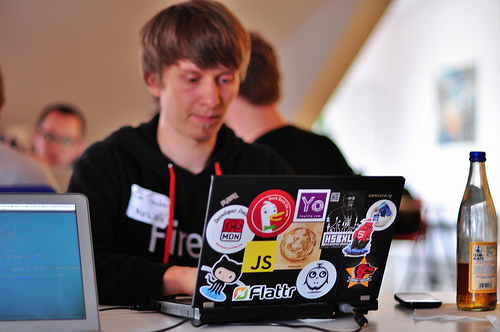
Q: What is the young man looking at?
A: Laptop.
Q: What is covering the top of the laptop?
A: Stickers.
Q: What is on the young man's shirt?
A: Sticker.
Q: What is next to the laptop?
A: Phone.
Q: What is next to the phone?
A: Beverage.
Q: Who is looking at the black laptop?
A: Young man.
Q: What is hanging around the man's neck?
A: Red string.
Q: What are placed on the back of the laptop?
A: Stickers.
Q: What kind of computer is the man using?
A: A laptop.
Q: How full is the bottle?
A: About half full.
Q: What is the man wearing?
A: A hoodie.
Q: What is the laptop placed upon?
A: A table.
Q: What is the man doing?
A: Typing.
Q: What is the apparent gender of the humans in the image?
A: Male.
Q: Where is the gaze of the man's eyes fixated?
A: The laptop screen.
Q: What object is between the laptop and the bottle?
A: A phone.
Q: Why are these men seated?
A: To be on their computers.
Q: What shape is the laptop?
A: Square.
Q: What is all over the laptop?
A: Stickers.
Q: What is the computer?
A: Laptop.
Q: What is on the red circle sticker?
A: Duck.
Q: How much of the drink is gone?
A: Half.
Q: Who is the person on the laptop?
A: Boy.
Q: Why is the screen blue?
A: On.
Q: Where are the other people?
A: Background.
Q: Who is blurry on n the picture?
A: The boy.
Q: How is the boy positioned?
A: Sitting.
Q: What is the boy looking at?
A: Laptop.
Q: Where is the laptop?
A: On the table.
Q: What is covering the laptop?
A: Stickers.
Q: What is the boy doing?
A: Working.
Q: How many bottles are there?
A: 1.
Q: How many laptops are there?
A: 2.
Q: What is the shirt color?
A: Black.